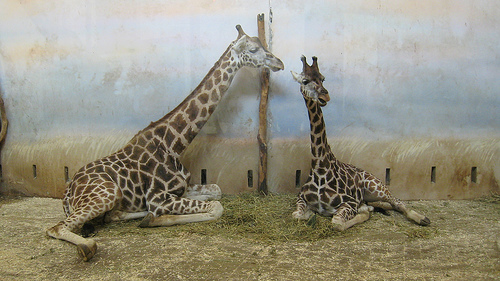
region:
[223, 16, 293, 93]
face of the zebra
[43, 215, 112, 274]
legs of the zebra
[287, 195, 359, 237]
front legs of zebra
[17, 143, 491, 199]
a black dotted lines in wall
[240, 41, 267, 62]
ear of the zebra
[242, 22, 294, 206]
a small wood in ground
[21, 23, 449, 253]
two zebras sitting in ground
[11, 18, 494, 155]
a beautiful white wall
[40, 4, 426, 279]
orange and white zebra laying down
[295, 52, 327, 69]
black and brown horns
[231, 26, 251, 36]
black and brown horns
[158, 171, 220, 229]
white bent legs on ground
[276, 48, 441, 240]
giraffe laying on ground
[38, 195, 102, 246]
leg of giraffe outstretched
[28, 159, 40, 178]
small hole in wall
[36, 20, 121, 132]
large concrete wall in background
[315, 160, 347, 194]
brown and white on griaffe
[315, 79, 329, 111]
small open mouth of giraffe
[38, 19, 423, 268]
two giraffes laying together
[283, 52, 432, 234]
smaller giraffe laying down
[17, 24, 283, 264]
larger giraffe laying down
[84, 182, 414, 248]
straw giraffes are laying on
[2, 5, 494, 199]
cement wall behind the giraffes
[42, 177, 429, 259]
folded legs of the giraffes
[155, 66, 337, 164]
long necks of the giraffe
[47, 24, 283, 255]
giraffe with his eyes closed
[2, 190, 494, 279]
ground the hay is on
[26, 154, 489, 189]
holes in foundation of the wall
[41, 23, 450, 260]
giraffes in front of a painted wall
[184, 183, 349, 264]
hay in a pile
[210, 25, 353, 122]
a giraffe looking at a young giraffe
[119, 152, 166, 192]
spots on a giraffe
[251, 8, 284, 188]
a piece of wood behind the giraffe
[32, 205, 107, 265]
leg of a giraffe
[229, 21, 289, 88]
the head of a giraffe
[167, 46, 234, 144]
the neck of a giraffe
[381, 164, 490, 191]
fence posts in a field on a painting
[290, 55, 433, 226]
Small giraffe sitting on the floor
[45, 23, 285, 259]
Big giraffe sitting on the floor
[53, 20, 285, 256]
Brown and white giraffe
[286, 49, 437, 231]
Brown and white giraffe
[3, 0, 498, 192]
Blue and brown painted wall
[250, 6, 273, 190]
Brown wooden pole next to wall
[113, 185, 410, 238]
Green and brown hay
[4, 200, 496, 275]
Brown floor with dirt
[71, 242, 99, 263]
hoof of the giraffe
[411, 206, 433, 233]
hoof of the giraffe